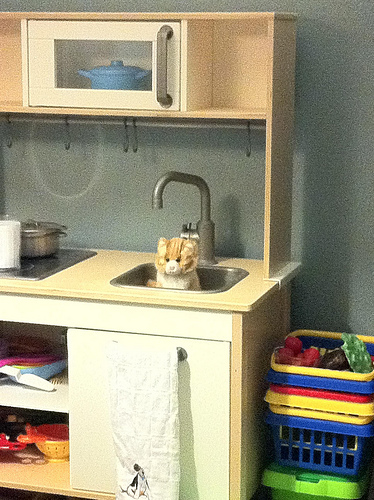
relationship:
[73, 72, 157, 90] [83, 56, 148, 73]
bowl has a lid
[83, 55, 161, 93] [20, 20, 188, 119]
teapot in microwave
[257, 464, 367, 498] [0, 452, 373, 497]
bin at bottom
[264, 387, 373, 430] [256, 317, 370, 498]
bins in stack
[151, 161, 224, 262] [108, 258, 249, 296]
faucet on sink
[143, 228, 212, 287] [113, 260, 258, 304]
animal in sink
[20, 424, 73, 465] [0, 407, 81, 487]
strainer in cabinet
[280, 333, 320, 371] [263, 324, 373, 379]
tomatoes in bin